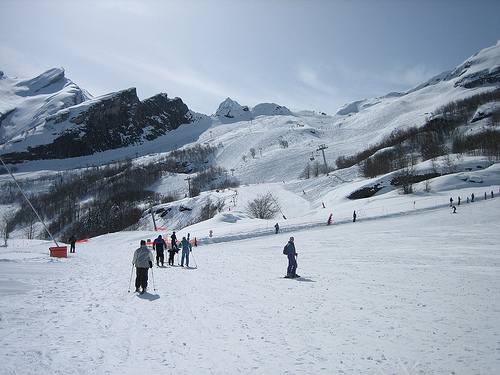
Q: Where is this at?
A: Ski slope.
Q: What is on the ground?
A: Snow.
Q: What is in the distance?
A: Hillside.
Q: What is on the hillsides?
A: Trees.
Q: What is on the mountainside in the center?
A: Ski resort.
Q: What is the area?
A: Mountainous.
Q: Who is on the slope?
A: Skiers.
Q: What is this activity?
A: Snow skiing.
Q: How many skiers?
A: At least 13.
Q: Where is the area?
A: In the mountains.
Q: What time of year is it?
A: Winter.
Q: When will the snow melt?
A: Spring.